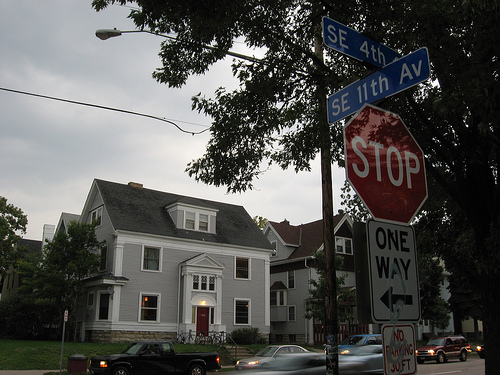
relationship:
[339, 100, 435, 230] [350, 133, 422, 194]
sign says stop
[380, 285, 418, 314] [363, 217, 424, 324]
arrow on sign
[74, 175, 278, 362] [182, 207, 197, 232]
house has window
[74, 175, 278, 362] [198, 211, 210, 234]
house has window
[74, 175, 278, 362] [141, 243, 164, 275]
house has window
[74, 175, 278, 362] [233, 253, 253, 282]
house has window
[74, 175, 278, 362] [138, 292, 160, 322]
house has window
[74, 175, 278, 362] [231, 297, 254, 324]
house has window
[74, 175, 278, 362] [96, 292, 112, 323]
house has window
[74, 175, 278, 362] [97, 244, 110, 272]
house has window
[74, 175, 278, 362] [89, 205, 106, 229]
house has window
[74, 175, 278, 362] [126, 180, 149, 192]
house has chimney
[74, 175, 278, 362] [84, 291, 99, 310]
house has window